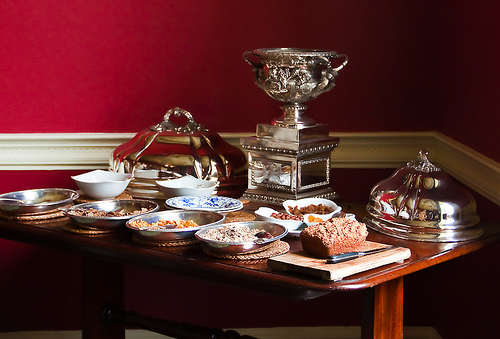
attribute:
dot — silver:
[238, 148, 312, 193]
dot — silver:
[255, 143, 265, 153]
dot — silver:
[255, 145, 260, 151]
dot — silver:
[302, 144, 311, 154]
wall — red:
[0, 4, 499, 134]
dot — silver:
[295, 147, 304, 155]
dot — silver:
[332, 190, 338, 195]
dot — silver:
[287, 148, 292, 153]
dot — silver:
[250, 145, 256, 149]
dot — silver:
[270, 147, 275, 151]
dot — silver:
[309, 147, 313, 152]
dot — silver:
[330, 144, 334, 147]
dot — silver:
[312, 145, 316, 151]